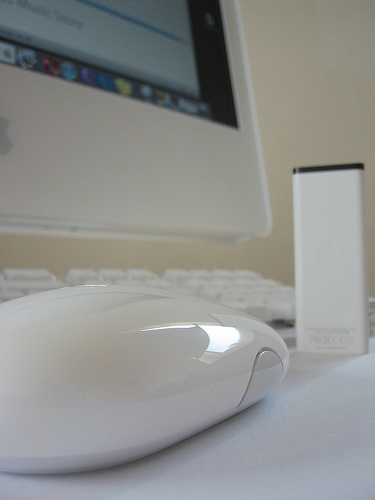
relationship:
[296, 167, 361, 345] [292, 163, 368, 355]
back of a box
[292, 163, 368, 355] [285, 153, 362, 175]
box with top